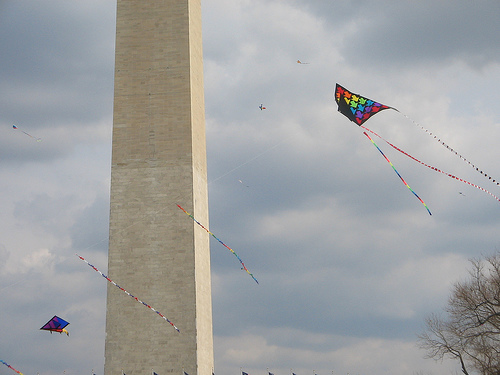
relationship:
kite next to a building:
[333, 83, 500, 220] [101, 0, 217, 370]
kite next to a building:
[37, 313, 72, 340] [101, 0, 217, 370]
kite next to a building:
[37, 313, 72, 340] [106, 5, 211, 372]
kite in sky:
[37, 313, 72, 340] [2, 0, 498, 370]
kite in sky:
[333, 83, 394, 125] [208, 4, 488, 339]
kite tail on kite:
[361, 124, 500, 215] [332, 85, 399, 135]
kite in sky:
[333, 83, 500, 220] [2, 0, 498, 370]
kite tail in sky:
[361, 124, 496, 207] [2, 0, 498, 370]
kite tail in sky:
[64, 241, 188, 334] [2, 0, 498, 370]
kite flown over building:
[333, 83, 500, 220] [101, 0, 216, 375]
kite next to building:
[176, 204, 259, 284] [101, 0, 217, 370]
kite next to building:
[333, 83, 500, 220] [101, 0, 217, 370]